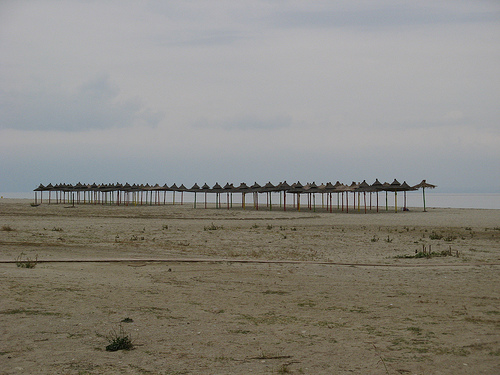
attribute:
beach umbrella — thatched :
[411, 172, 439, 221]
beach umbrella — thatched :
[400, 178, 416, 215]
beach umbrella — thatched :
[387, 178, 400, 210]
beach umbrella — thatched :
[337, 178, 354, 209]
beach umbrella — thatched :
[321, 180, 340, 224]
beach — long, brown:
[22, 191, 476, 241]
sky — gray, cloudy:
[23, 17, 480, 177]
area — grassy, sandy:
[220, 275, 446, 357]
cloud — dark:
[109, 24, 474, 174]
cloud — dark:
[110, 104, 331, 165]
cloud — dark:
[116, 9, 246, 79]